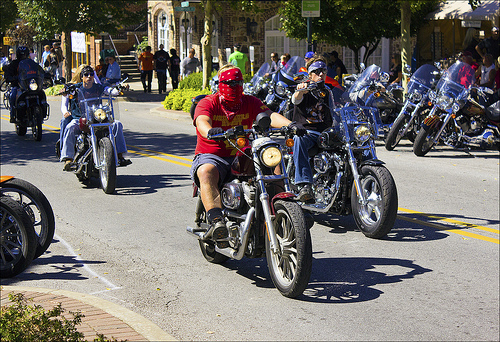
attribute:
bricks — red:
[70, 300, 101, 339]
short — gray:
[187, 149, 236, 196]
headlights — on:
[81, 97, 387, 182]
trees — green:
[23, 3, 416, 44]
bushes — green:
[172, 82, 204, 110]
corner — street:
[150, 97, 195, 120]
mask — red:
[213, 60, 248, 104]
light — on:
[262, 143, 282, 166]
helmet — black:
[80, 63, 95, 77]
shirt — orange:
[138, 49, 158, 75]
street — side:
[0, 84, 498, 340]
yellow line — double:
[5, 103, 499, 250]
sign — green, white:
[300, 0, 318, 21]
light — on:
[258, 139, 288, 173]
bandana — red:
[212, 62, 246, 103]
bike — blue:
[58, 77, 135, 191]